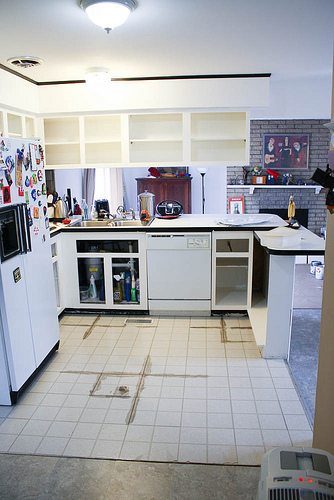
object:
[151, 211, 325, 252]
countertop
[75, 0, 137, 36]
light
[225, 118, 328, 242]
brick fireplace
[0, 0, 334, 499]
kitchen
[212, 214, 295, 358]
cabinets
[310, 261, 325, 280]
paint cans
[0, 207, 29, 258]
ice dispenser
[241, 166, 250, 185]
item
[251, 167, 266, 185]
item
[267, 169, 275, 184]
item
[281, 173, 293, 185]
item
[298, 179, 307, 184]
item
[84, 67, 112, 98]
light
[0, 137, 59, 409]
fridge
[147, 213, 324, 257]
counter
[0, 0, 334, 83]
ceiling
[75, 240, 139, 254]
cabinet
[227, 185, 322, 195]
mantel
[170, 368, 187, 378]
tiles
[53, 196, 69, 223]
kettle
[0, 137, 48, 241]
magnets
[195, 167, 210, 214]
lamp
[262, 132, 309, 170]
art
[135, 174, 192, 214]
cabinet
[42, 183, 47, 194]
magnets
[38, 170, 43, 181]
magnets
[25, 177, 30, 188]
magnets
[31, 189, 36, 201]
magnets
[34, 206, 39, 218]
magnets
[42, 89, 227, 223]
wall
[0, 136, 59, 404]
refrigerator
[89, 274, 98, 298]
bottle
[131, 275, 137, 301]
bottle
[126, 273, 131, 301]
bottle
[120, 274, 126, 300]
bottle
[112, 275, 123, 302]
bottle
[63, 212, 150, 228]
sink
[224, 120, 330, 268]
wall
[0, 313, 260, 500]
floor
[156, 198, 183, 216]
radio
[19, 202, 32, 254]
handle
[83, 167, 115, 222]
window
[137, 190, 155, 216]
pot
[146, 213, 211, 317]
counter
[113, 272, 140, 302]
cleaning products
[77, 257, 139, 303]
cabinet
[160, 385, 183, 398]
tile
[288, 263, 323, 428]
floor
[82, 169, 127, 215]
curtain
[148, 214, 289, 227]
kitchen counter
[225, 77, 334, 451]
room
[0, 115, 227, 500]
room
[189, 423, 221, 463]
grout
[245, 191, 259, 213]
bricks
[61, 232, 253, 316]
bottom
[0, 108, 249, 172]
cabinet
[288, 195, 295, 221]
dish washing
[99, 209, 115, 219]
faucet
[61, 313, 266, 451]
tiles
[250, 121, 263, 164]
bricks